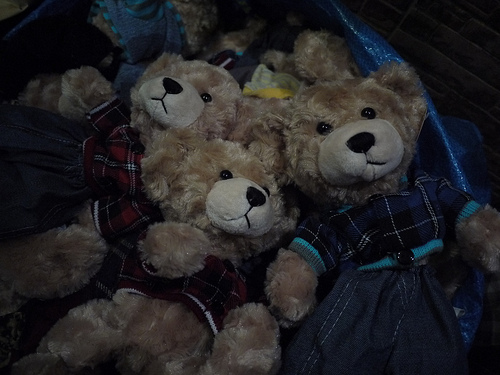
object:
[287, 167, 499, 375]
cloth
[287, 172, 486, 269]
sweater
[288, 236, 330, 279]
edge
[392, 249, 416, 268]
button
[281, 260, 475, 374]
shorts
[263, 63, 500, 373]
teddy bear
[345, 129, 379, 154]
nose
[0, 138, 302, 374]
teddy bear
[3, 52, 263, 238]
teddy bear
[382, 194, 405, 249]
line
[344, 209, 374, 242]
line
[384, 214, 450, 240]
line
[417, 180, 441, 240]
line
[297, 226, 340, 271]
line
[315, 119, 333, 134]
eye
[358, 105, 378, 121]
eye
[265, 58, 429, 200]
head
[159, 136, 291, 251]
head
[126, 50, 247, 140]
head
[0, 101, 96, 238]
pants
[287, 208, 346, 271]
sleeve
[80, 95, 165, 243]
shirt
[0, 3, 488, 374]
bag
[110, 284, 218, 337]
stripe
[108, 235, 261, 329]
sweater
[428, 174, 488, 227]
sleeve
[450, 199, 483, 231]
trim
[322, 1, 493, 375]
edge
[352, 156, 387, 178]
mouth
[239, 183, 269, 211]
nose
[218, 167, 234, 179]
eye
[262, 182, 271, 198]
eye